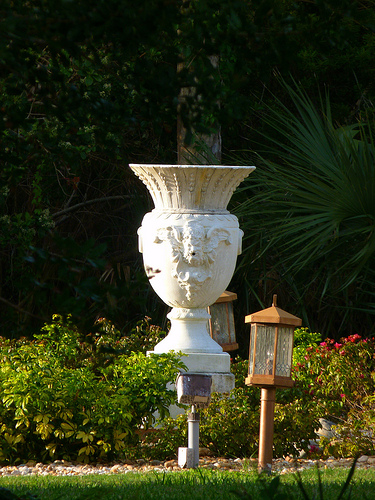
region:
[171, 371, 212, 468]
spotlight on metal stand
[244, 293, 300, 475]
light in front of urn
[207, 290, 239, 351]
light behind the urn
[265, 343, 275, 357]
light bulb inside front light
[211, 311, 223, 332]
light bulb inside back light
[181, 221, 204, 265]
sculture of face on urn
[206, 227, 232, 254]
right wing on urn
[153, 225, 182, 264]
left wing on urn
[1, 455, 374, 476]
row of gravelbehind grass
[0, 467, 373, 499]
small row of grass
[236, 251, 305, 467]
small octagonal yard light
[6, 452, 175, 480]
light colored smooth pebbles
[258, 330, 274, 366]
a small light bulb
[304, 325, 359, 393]
bush with pink and red flowers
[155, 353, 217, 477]
a back-facing spotlight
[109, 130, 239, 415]
a large stone birdbath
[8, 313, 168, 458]
a small green bush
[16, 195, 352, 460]
a dark green thicket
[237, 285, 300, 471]
light brown yard accessory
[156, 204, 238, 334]
intricate detail carving on stone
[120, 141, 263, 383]
Large concrete vase towards the front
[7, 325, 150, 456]
Large group of bushes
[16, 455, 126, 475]
Gravel underneath a group of bushes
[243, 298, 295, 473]
A lamp on a stake in the grass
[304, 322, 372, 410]
Bush with pink flowers on it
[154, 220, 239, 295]
Vase has a pattern on it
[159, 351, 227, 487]
Spotlight pointed towards the vase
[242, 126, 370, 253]
Large palm tree in the background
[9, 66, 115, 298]
Group of trees in the forest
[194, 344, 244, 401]
water stains on base of vase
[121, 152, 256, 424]
The large white structure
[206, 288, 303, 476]
The two small gold lights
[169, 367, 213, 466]
The single white and brown light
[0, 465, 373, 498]
The grass around the white structure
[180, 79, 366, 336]
The palm tree behind the statue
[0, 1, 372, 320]
The trees behind the small palm tree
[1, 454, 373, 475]
The gravel around the statue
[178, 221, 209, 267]
The face of the statue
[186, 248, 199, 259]
The hole in the mouth of the statue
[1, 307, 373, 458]
The short plants with red flowers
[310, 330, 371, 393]
Green plant with pink flowers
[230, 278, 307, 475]
Bronze outside light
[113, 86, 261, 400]
White outdoor water fountain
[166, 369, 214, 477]
Black and silver light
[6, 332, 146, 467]
Thick green shrubbery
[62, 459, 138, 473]
White and tan oval rocks.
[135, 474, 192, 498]
Tall green grass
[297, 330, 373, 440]
Hot pink flowers and green leaves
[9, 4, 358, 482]
Beautiful symmetrical landscape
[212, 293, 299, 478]
Pair of bronze outdoor lights